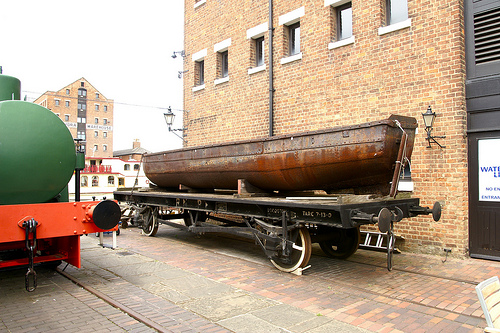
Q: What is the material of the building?
A: Brick.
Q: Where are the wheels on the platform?
A: On the ground.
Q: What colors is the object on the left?
A: Green and orange.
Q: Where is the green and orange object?
A: On the left.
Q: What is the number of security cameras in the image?
A: One.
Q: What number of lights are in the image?
A: Two.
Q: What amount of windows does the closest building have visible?
A: Six.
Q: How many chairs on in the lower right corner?
A: One.